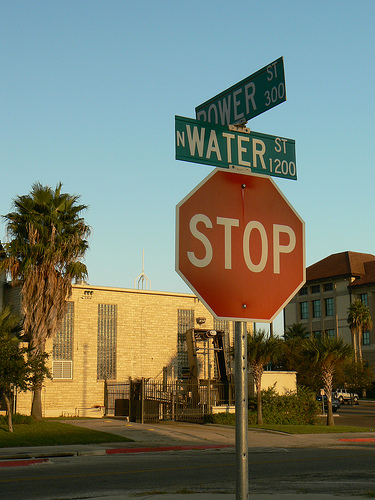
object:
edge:
[4, 491, 374, 500]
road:
[0, 448, 375, 498]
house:
[283, 251, 374, 396]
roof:
[304, 251, 374, 290]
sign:
[174, 166, 306, 323]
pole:
[234, 320, 249, 499]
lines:
[0, 452, 374, 484]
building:
[7, 281, 298, 417]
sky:
[0, 0, 375, 341]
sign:
[175, 115, 298, 181]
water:
[185, 123, 267, 169]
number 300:
[265, 82, 285, 107]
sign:
[195, 55, 287, 128]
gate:
[129, 376, 253, 424]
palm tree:
[0, 180, 92, 418]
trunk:
[32, 365, 43, 418]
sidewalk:
[1, 442, 374, 467]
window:
[53, 301, 74, 379]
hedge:
[203, 385, 320, 425]